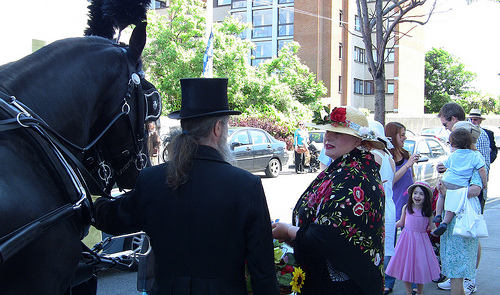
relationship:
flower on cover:
[306, 104, 382, 145] [305, 105, 388, 150]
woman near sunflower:
[272, 103, 387, 293] [290, 266, 306, 292]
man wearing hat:
[148, 56, 303, 288] [166, 75, 246, 121]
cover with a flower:
[305, 105, 388, 150] [326, 106, 347, 123]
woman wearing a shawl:
[272, 103, 387, 293] [304, 163, 398, 272]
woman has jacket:
[272, 103, 387, 293] [294, 150, 376, 285]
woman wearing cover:
[272, 103, 387, 293] [305, 105, 388, 150]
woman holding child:
[408, 117, 461, 288] [440, 121, 489, 231]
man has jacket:
[93, 75, 274, 295] [97, 143, 276, 293]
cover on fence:
[305, 105, 388, 150] [378, 113, 497, 133]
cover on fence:
[334, 111, 463, 137] [283, 77, 435, 149]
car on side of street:
[225, 123, 289, 180] [170, 150, 457, 227]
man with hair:
[93, 75, 274, 295] [163, 106, 204, 192]